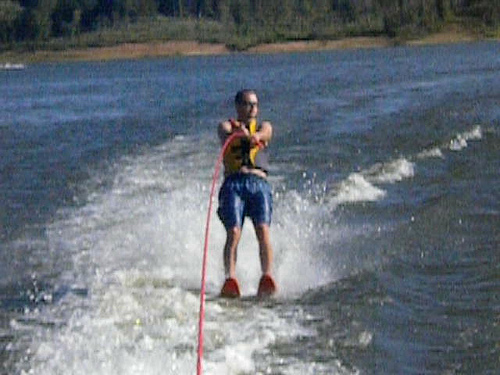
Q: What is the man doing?
A: Waterskiing.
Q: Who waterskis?
A: Water Skiers.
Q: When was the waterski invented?
A: 1922.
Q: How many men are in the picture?
A: One.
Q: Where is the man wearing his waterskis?
A: On his feet.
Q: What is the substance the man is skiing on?
A: Water.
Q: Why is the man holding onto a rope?
A: To ski.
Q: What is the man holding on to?
A: A rope.